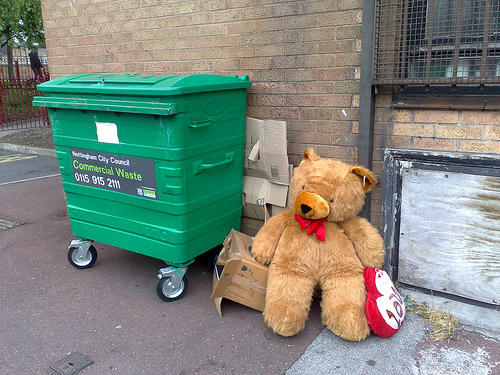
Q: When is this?
A: Daytime.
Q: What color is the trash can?
A: Green.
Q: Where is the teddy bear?
A: By the trash can.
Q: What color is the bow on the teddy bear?
A: Red.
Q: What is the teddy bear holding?
A: A heart.